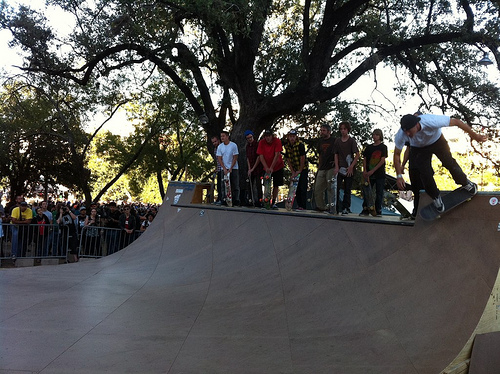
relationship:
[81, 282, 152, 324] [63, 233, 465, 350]
line on ramp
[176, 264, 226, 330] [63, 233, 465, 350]
line on ramp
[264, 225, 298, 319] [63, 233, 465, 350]
line on ramp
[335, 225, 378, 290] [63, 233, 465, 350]
line on ramp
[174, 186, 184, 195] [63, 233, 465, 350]
sticker on ramp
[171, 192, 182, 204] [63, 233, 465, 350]
sticker on ramp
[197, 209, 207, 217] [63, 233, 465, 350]
sticker on ramp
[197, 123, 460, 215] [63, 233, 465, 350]
skateboarders on ramp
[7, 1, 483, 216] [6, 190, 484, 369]
tree behind ramp